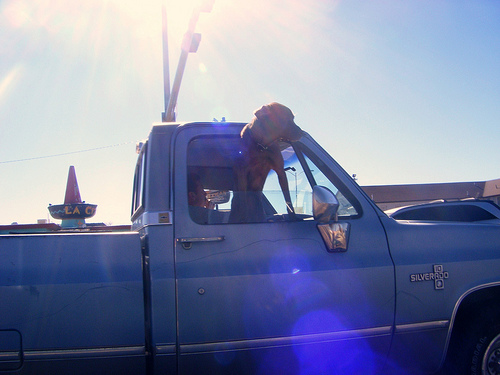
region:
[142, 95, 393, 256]
brown dog in window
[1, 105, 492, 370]
the truck is blue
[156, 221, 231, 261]
the door handle on the truck is silver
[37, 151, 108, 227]
a mexican restaurant sign by truck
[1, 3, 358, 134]
sun is shining by sign post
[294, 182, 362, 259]
the blue truck has a silver mirror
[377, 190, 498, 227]
a vehicle by the truck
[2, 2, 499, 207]
the sky is bright and blue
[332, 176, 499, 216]
a building past the vehicles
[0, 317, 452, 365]
the blue truck has a silver stripe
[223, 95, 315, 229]
a dog is looking out truck window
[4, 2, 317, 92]
sun rays are visible in the sky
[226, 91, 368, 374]
lens flare circles on photo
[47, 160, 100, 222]
a mexican hat sign in the distance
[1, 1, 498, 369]
photo was taken outdoors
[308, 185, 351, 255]
rear view mirror on side of truck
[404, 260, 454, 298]
model logo on side of vehicle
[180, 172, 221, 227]
the driver is looking ahead in front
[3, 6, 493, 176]
the sky is cloudless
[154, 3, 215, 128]
a light pole is behind the vehicle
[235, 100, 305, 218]
a dog sticking his head out of a truck's window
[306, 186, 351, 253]
the side view mirror on a truck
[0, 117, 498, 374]
a blue pickup truck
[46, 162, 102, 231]
a sombrero statue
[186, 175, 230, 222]
The driver of a pickup truck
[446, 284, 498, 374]
the front right wheel of a pickup truck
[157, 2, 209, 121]
a traffic signal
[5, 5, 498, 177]
a cloudy sky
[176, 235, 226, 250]
the door handle of a pickup truck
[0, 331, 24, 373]
the gas tank of a pickup truck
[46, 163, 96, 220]
Mexican sombrero in the back of the truck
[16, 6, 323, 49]
Bright sun in the sky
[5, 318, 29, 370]
Gas tank in the bed of the truck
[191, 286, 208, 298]
Key hole in the door of the truck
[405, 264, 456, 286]
Silverado emblem on the side of the truck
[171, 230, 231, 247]
Door handle on the side of the truck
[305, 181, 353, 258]
Passenger side rear view mirror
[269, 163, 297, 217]
Left leg of the dog in the window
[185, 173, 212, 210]
Driver inside of the truck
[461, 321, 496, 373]
Right front tire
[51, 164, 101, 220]
red black yellow and blue sombrero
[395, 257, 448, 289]
small metal silverado truck plate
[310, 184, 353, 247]
chrome side view truck mirror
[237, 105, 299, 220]
large tan brown dog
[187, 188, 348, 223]
bluish glass window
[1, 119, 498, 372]
light blue old truck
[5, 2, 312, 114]
bright sunshine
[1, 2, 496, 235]
very clear blue sky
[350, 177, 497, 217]
brown roof of building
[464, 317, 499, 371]
truck tire